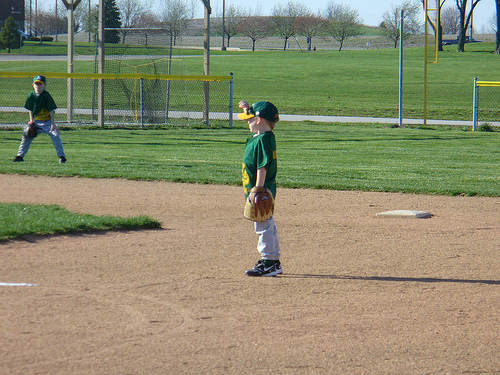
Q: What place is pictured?
A: It is a field.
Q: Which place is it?
A: It is a field.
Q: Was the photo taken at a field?
A: Yes, it was taken in a field.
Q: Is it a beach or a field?
A: It is a field.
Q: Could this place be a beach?
A: No, it is a field.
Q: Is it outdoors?
A: Yes, it is outdoors.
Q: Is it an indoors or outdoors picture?
A: It is outdoors.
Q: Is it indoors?
A: No, it is outdoors.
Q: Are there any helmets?
A: No, there are no helmets.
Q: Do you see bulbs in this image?
A: No, there are no bulbs.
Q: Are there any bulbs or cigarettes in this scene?
A: No, there are no bulbs or cigarettes.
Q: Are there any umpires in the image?
A: No, there are no umpires.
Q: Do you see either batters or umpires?
A: No, there are no umpires or batters.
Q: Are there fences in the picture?
A: Yes, there is a fence.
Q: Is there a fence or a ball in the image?
A: Yes, there is a fence.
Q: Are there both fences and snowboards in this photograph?
A: No, there is a fence but no snowboards.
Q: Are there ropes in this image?
A: No, there are no ropes.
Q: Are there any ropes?
A: No, there are no ropes.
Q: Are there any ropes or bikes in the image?
A: No, there are no ropes or bikes.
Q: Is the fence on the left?
A: Yes, the fence is on the left of the image.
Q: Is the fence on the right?
A: No, the fence is on the left of the image.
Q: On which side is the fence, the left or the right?
A: The fence is on the left of the image.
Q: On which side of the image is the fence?
A: The fence is on the left of the image.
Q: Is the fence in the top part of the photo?
A: Yes, the fence is in the top of the image.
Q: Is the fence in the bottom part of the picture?
A: No, the fence is in the top of the image.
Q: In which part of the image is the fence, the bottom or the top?
A: The fence is in the top of the image.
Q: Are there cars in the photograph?
A: No, there are no cars.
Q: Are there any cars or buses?
A: No, there are no cars or buses.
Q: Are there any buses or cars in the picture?
A: No, there are no cars or buses.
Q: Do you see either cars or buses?
A: No, there are no cars or buses.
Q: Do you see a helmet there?
A: No, there are no helmets.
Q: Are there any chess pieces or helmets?
A: No, there are no helmets or chess pieces.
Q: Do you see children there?
A: Yes, there is a child.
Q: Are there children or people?
A: Yes, there is a child.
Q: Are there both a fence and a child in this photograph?
A: Yes, there are both a child and a fence.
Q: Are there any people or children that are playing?
A: Yes, the child is playing.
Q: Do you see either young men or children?
A: Yes, there is a young child.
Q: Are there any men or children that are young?
A: Yes, the child is young.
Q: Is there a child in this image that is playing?
A: Yes, there is a child that is playing.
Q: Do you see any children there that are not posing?
A: Yes, there is a child that is playing .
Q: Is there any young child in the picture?
A: Yes, there is a young child.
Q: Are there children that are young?
A: Yes, there is a child that is young.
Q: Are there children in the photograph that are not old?
A: Yes, there is an young child.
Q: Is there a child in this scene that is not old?
A: Yes, there is an young child.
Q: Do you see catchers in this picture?
A: No, there are no catchers.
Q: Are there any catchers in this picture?
A: No, there are no catchers.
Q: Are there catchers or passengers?
A: No, there are no catchers or passengers.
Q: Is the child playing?
A: Yes, the child is playing.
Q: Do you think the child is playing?
A: Yes, the child is playing.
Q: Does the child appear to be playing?
A: Yes, the child is playing.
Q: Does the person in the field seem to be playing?
A: Yes, the child is playing.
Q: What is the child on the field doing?
A: The kid is playing.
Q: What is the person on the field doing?
A: The kid is playing.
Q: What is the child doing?
A: The kid is playing.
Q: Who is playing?
A: The kid is playing.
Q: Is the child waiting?
A: No, the child is playing.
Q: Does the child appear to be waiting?
A: No, the child is playing.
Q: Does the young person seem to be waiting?
A: No, the child is playing.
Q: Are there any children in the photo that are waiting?
A: No, there is a child but he is playing.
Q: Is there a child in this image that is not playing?
A: No, there is a child but he is playing.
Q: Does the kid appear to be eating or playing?
A: The kid is playing.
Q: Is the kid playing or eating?
A: The kid is playing.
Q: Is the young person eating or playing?
A: The kid is playing.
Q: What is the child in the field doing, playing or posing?
A: The child is playing.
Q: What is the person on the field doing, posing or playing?
A: The child is playing.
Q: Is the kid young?
A: Yes, the kid is young.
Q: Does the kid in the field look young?
A: Yes, the child is young.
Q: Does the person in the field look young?
A: Yes, the child is young.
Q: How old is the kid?
A: The kid is young.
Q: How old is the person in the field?
A: The kid is young.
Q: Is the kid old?
A: No, the kid is young.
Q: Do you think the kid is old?
A: No, the kid is young.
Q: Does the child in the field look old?
A: No, the kid is young.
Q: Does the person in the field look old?
A: No, the kid is young.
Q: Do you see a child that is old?
A: No, there is a child but he is young.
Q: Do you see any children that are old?
A: No, there is a child but he is young.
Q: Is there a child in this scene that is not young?
A: No, there is a child but he is young.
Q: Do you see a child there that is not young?
A: No, there is a child but he is young.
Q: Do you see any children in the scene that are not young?
A: No, there is a child but he is young.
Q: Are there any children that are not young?
A: No, there is a child but he is young.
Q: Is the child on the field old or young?
A: The kid is young.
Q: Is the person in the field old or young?
A: The kid is young.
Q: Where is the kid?
A: The kid is in the field.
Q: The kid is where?
A: The kid is in the field.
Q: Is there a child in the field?
A: Yes, there is a child in the field.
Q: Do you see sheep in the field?
A: No, there is a child in the field.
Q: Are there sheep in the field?
A: No, there is a child in the field.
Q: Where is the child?
A: The child is on the field.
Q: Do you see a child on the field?
A: Yes, there is a child on the field.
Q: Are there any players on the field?
A: No, there is a child on the field.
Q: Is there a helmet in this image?
A: No, there are no helmets.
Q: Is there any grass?
A: Yes, there is grass.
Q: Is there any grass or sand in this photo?
A: Yes, there is grass.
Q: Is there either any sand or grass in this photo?
A: Yes, there is grass.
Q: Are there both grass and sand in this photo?
A: No, there is grass but no sand.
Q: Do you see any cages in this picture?
A: No, there are no cages.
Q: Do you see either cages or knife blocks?
A: No, there are no cages or knife blocks.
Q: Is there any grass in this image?
A: Yes, there is grass.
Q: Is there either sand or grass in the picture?
A: Yes, there is grass.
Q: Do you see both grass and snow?
A: No, there is grass but no snow.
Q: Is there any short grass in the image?
A: Yes, there is short grass.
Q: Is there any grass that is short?
A: Yes, there is grass that is short.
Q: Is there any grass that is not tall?
A: Yes, there is short grass.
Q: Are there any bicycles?
A: No, there are no bicycles.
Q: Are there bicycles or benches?
A: No, there are no bicycles or benches.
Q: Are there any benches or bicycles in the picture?
A: No, there are no bicycles or benches.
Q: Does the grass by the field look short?
A: Yes, the grass is short.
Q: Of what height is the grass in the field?
A: The grass is short.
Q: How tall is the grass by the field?
A: The grass is short.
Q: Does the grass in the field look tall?
A: No, the grass is short.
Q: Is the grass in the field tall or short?
A: The grass is short.